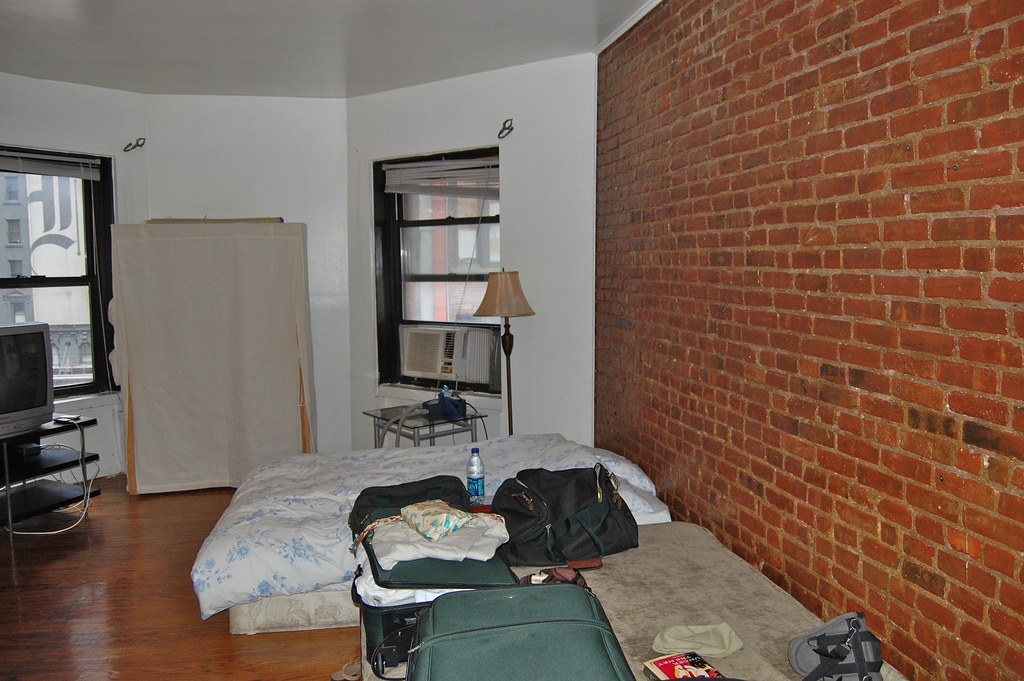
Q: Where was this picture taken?
A: In a bedroom.